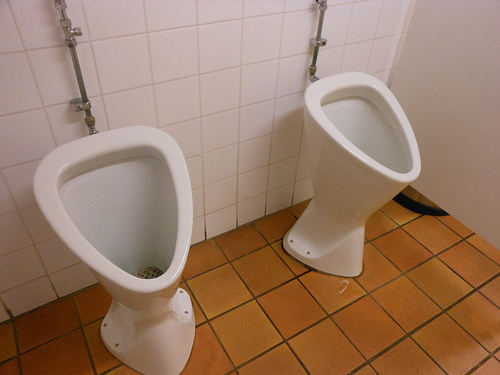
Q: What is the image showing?
A: It is showing a bathroom.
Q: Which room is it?
A: It is a bathroom.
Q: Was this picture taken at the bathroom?
A: Yes, it was taken in the bathroom.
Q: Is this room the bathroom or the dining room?
A: It is the bathroom.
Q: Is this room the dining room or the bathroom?
A: It is the bathroom.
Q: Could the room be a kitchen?
A: No, it is a bathroom.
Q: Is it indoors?
A: Yes, it is indoors.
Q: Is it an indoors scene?
A: Yes, it is indoors.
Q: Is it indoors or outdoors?
A: It is indoors.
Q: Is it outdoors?
A: No, it is indoors.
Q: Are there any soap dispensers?
A: No, there are no soap dispensers.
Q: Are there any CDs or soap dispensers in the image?
A: No, there are no soap dispensers or cds.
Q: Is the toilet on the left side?
A: No, the toilet is on the right of the image.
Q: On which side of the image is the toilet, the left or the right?
A: The toilet is on the right of the image.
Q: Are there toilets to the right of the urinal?
A: Yes, there is a toilet to the right of the urinal.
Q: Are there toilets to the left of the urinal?
A: No, the toilet is to the right of the urinal.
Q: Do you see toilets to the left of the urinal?
A: No, the toilet is to the right of the urinal.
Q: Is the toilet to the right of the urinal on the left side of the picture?
A: Yes, the toilet is to the right of the urinal.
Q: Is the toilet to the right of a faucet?
A: No, the toilet is to the right of the urinal.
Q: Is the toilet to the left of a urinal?
A: No, the toilet is to the right of a urinal.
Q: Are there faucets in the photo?
A: No, there are no faucets.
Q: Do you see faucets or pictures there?
A: No, there are no faucets or pictures.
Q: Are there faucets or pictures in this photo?
A: No, there are no faucets or pictures.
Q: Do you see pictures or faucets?
A: No, there are no faucets or pictures.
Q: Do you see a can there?
A: Yes, there is a can.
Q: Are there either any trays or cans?
A: Yes, there is a can.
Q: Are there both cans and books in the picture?
A: No, there is a can but no books.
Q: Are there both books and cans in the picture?
A: No, there is a can but no books.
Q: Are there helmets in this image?
A: No, there are no helmets.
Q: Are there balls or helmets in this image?
A: No, there are no helmets or balls.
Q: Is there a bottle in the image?
A: No, there are no bottles.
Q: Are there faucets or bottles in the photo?
A: No, there are no bottles or faucets.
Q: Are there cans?
A: Yes, there is a can.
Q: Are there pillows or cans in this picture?
A: Yes, there is a can.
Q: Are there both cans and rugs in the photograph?
A: No, there is a can but no rugs.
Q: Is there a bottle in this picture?
A: No, there are no bottles.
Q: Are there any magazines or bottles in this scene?
A: No, there are no bottles or magazines.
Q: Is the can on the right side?
A: Yes, the can is on the right of the image.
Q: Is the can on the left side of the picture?
A: No, the can is on the right of the image.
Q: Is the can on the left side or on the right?
A: The can is on the right of the image.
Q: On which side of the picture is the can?
A: The can is on the right of the image.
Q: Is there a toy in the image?
A: No, there are no toys.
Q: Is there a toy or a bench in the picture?
A: No, there are no toys or benches.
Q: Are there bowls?
A: No, there are no bowls.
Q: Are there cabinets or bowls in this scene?
A: No, there are no bowls or cabinets.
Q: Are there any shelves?
A: No, there are no shelves.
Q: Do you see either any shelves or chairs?
A: No, there are no shelves or chairs.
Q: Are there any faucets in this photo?
A: No, there are no faucets.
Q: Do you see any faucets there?
A: No, there are no faucets.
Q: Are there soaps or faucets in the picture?
A: No, there are no faucets or soaps.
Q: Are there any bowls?
A: No, there are no bowls.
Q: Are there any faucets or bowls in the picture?
A: No, there are no bowls or faucets.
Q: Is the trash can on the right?
A: Yes, the trash can is on the right of the image.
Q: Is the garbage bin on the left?
A: No, the garbage bin is on the right of the image.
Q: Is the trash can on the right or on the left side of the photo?
A: The trash can is on the right of the image.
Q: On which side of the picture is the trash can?
A: The trash can is on the right of the image.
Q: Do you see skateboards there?
A: No, there are no skateboards.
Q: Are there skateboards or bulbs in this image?
A: No, there are no skateboards or bulbs.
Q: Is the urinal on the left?
A: Yes, the urinal is on the left of the image.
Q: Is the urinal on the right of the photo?
A: No, the urinal is on the left of the image.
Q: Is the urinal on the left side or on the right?
A: The urinal is on the left of the image.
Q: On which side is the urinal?
A: The urinal is on the left of the image.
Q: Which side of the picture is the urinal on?
A: The urinal is on the left of the image.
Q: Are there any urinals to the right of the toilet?
A: No, the urinal is to the left of the toilet.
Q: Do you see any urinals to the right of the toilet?
A: No, the urinal is to the left of the toilet.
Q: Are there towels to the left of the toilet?
A: No, there is a urinal to the left of the toilet.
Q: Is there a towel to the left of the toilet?
A: No, there is a urinal to the left of the toilet.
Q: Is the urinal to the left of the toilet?
A: Yes, the urinal is to the left of the toilet.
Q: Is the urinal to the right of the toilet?
A: No, the urinal is to the left of the toilet.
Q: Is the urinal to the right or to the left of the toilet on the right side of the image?
A: The urinal is to the left of the toilet.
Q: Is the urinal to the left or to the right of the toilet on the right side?
A: The urinal is to the left of the toilet.